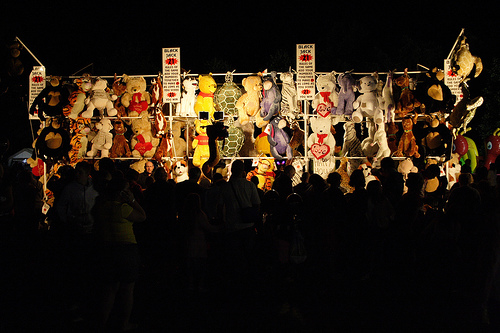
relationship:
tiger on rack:
[66, 76, 91, 115] [18, 23, 483, 224]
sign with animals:
[294, 42, 317, 100] [28, 73, 66, 116]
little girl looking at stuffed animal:
[173, 188, 221, 294] [254, 72, 280, 119]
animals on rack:
[38, 79, 157, 117] [65, 67, 162, 83]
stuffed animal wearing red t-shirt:
[185, 118, 214, 168] [194, 135, 209, 146]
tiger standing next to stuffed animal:
[66, 76, 91, 115] [308, 71, 338, 116]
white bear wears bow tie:
[310, 71, 342, 116] [319, 90, 331, 106]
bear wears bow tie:
[303, 111, 333, 163] [316, 132, 326, 146]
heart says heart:
[309, 139, 333, 163] [309, 142, 330, 161]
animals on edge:
[28, 73, 66, 116] [20, 74, 52, 166]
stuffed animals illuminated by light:
[80, 63, 446, 190] [129, 67, 335, 175]